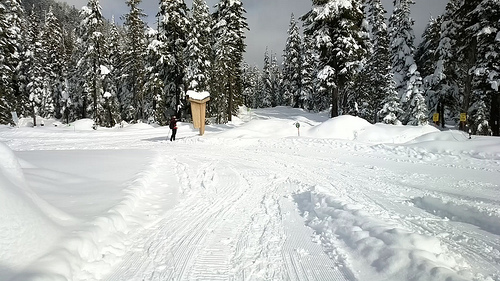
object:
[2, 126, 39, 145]
snow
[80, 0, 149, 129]
trees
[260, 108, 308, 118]
snow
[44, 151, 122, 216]
drifted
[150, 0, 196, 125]
evergreens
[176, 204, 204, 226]
snow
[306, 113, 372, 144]
snow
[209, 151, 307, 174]
snow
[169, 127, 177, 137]
leg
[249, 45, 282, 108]
trees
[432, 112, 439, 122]
signs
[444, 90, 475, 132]
ground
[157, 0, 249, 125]
tree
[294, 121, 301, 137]
marker pole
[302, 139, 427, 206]
traffic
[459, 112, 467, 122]
board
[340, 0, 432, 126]
tree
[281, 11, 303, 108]
tree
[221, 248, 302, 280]
snow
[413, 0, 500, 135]
pine trees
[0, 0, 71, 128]
covered tree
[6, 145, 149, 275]
snow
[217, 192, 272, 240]
snow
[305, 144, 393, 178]
snow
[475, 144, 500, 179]
snow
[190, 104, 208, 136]
pillar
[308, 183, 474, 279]
snow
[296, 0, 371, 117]
tree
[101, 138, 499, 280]
path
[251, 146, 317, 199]
snow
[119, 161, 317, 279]
tracks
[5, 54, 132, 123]
snow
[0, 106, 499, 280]
ground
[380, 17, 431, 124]
snow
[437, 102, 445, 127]
pillar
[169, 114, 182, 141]
person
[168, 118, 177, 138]
snowsuit